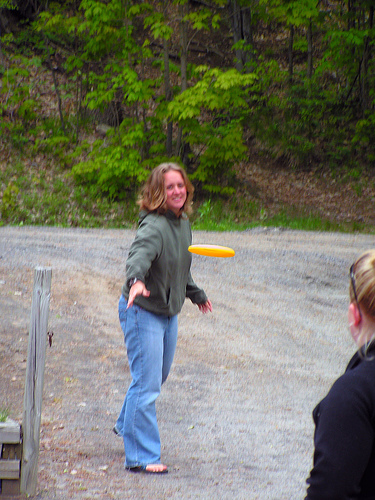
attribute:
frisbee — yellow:
[183, 231, 249, 265]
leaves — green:
[158, 74, 252, 108]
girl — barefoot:
[123, 161, 209, 477]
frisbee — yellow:
[186, 242, 235, 258]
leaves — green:
[137, 78, 261, 148]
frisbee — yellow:
[179, 238, 262, 283]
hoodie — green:
[131, 215, 191, 302]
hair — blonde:
[350, 252, 373, 313]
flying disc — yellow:
[186, 243, 236, 256]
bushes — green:
[0, 0, 373, 203]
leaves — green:
[299, 18, 375, 155]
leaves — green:
[154, 55, 263, 174]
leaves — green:
[38, 13, 194, 130]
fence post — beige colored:
[17, 267, 58, 498]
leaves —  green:
[252, 79, 287, 134]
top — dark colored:
[303, 341, 363, 498]